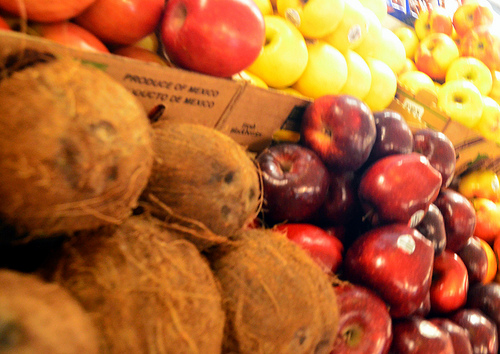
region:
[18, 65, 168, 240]
a brown coconut shell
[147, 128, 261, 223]
a brown coconut shell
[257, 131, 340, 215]
the apple is overripe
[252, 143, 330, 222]
apple is next to apple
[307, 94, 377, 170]
apple is next to apple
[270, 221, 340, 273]
apple is next to apple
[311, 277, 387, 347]
apple is next to apple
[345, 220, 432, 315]
apple is next to apple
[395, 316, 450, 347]
apple is next to apple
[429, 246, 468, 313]
apple is next to apple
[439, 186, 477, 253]
apple is next to apple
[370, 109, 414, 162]
apple is next to apple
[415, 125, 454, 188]
apple is next to apple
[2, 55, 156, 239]
one coconut in fruit sand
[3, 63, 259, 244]
two coconut on fruit stand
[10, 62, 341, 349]
a bunch of coconuts on fruit stand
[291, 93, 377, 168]
a red apple on fruit stand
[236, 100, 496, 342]
a bunch of red apples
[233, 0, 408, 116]
a box of apples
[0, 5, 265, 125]
a box of apples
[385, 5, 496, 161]
a box of sour apples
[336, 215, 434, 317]
sticker on the apple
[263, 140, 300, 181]
stem of an apple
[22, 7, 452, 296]
fruit at a stand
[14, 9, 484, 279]
this fruit is on display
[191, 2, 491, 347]
this fruit is being sold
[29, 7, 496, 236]
a lot of fruit for sale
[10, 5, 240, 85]
apples in a box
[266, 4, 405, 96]
yellow apples for sale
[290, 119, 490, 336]
red apples piled up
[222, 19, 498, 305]
these apples look fresh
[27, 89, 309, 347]
coconuts for sale to shoppers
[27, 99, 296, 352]
these fruit have hair on their shells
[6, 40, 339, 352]
a bunch of coconuts on display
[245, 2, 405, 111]
a bunch of yellow apples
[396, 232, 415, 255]
a white sticker on an apple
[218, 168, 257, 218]
three holes in a coconut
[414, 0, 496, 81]
yellow and red apples on display in a fruit stall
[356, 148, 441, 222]
a red apple upside down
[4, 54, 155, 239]
a coconut on top of another coconut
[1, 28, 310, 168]
brown cardboard boxes holding apples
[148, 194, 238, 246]
brown filaments of a cocunut